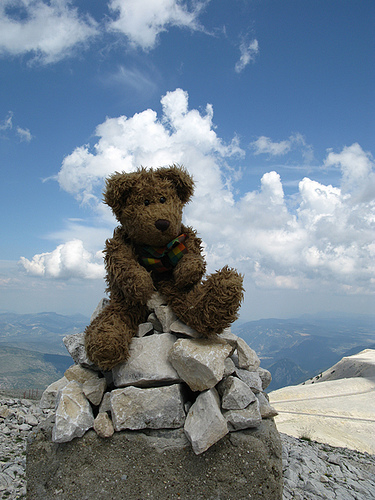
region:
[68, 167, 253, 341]
a shaggy brown teddy bear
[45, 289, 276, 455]
a pile of rocks under a teddy bear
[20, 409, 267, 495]
a concrete base supporting a pile of rocks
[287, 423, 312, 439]
grass growing on the edge of th rocks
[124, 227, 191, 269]
a ribbon on a teddy bear's neck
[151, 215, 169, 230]
a dark brown teddy bear nose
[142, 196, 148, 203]
a black eye on a teddy bear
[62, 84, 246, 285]
a white puffy cloud behind a teddy bear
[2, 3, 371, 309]
a beautiful blue sky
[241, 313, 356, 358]
mountains in the distance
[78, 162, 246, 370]
Brown fuzzy teddy bear.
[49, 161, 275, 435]
Brown teddy bear sitting on top of the rocks.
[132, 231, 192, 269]
Multicolored scarf tied around the bears neck.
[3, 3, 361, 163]
Blue sky filled with clouds.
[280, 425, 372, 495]
Ground covered in grey slated rocks.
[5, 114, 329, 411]
View from the top of a mountain.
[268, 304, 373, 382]
Valley of mountains below.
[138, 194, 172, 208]
Black eyes of the teddy bear.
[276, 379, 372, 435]
Ground covered in white rock.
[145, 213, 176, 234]
Black nose of the teddy bear.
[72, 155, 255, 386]
a teddy bear sits on rocks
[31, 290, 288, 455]
a pile of rocks under a bear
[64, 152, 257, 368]
teddy bear is brown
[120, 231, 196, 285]
teddy bear has a necktie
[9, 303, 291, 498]
small rocks ona big stone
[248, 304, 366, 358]
mountains in the background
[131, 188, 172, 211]
eyes of teddy bear are close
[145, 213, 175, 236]
nose of teddy is brown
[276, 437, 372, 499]
rocks on right side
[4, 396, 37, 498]
small rocks on left side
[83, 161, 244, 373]
a brown plush teddy bear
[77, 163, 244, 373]
a teddy bear wearing a bow tie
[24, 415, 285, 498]
a large grey stone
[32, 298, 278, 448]
a pile of white rocks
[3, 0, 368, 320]
a cloudy blue sky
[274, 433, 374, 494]
white rocky terrain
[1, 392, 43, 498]
white rocky terrain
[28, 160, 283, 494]
a teddy bear sitting on a pile of rocks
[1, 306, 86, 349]
mountains in far distance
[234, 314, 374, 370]
mountains in far distance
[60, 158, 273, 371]
teddy bear on top of rocks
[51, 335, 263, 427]
white rocks on top of a boulder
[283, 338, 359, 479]
white road on top of the mountain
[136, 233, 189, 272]
plaid bow tie on the teddy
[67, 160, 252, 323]
brown teddy with messy fur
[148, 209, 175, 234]
brown nose on a brown teddy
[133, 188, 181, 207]
black beady eyes of a teddy bear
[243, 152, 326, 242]
fluffy white clouds in the sky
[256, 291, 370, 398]
white road much higher that the countryside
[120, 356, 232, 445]
pile of white rocks